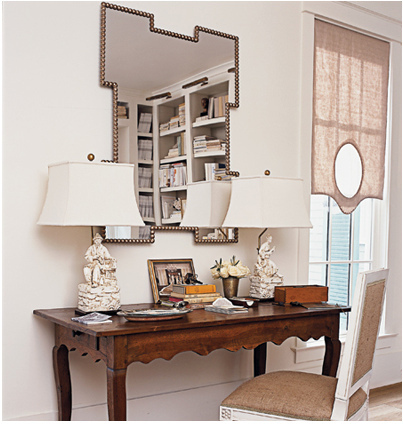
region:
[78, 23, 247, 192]
a mirror hanging on a wall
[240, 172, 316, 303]
a lamp on a table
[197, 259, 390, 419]
a desk chair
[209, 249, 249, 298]
a small vase of flowers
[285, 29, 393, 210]
a curtain on a door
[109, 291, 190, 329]
a plate on a table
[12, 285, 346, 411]
a brown wooden table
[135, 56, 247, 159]
the reflection of a book shelf in a mirror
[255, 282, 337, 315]
a small wooden box on a table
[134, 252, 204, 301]
a picture leaning on a wall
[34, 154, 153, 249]
the shade is white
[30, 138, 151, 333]
the lamp is white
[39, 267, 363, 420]
the table is brown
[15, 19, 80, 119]
the wall is white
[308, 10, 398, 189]
the curtain is white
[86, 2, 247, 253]
the mirror is on the wall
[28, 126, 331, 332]
there are two lamps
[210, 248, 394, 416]
the chair is empty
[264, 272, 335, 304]
the box is brown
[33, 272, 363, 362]
the table is long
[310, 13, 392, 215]
Tan curtain with circle cut out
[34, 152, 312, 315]
Two white statue lamps with brass balls on top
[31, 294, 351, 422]
Brown wooden desk with small drawer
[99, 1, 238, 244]
Large geometric mirror with brass dots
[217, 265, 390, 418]
Tan and white chair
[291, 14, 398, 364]
Large long window with bars and dressing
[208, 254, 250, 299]
White flowers in brass vase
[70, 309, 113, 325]
Small book on brown desk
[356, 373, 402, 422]
Wood floor under window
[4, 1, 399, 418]
White walls and floor boards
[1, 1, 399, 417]
the wall is painted white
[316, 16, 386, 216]
the shade is beige in color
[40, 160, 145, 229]
the lamp shade is white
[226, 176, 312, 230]
the lamp shade is white in color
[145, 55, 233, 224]
the bookcase is reflecting on the mirror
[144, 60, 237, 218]
the bookcase is white in color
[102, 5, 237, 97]
the ceiling is painted white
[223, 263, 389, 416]
the chair frame is white in color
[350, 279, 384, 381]
the backrest is taupe in color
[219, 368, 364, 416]
the chair is seat in color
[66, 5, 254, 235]
white geometric shaped mirror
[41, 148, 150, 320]
white lampshade and sculpture base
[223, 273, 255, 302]
gold bucket with white roses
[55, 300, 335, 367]
brown wooden desk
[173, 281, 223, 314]
stack of books on desk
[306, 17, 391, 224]
roman beige shade with keyhole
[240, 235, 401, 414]
white chair with burlap seats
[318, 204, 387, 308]
ceiling to floor windows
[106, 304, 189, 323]
antique blue and gold dish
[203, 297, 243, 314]
small notepad for desk